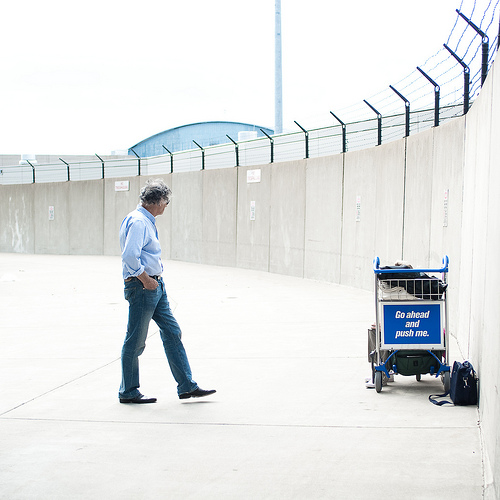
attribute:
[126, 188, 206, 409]
man — walking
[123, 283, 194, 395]
jeans — blue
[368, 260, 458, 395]
cart — metal, blue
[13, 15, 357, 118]
sky — white, overcast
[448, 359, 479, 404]
bag — black, blue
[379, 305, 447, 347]
sign — push me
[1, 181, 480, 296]
wall — large, cement, concrete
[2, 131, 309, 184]
wire — barb, bard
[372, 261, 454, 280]
handle — blue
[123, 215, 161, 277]
shirt — light blue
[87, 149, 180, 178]
rods — bend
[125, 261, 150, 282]
sleeve — rolled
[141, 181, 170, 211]
hair — grey, bald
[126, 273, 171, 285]
belt — brown, leather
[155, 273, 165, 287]
buckle — gold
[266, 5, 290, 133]
smoke stack — tall, concrete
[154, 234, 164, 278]
button — light blue